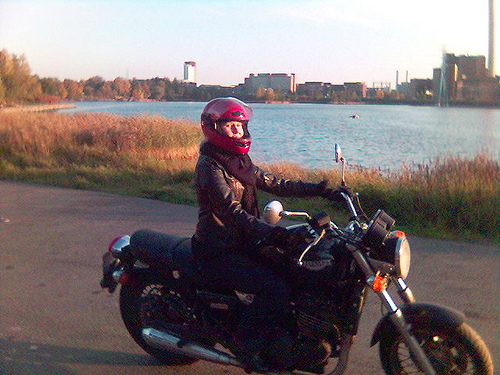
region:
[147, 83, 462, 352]
A person on a motorcycle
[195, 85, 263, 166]
A person wearing a helmet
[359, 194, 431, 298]
The headlight on a motorcycle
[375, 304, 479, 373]
The front tire on a motorcycle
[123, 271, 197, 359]
The rear tire on a motorcycle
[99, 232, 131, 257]
The break light on a motorcycle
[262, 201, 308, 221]
The mirror on a motorcycle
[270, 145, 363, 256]
The handle bars on a motorcycle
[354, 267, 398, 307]
The turn signal on a motorcycle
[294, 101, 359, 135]
Water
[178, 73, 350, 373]
Woman riding a motorcycle.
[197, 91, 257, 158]
Woman wearing red helmet.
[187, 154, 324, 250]
Woman dressed in brown leather jacket.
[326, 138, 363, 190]
Rear view mirror on motorcycle.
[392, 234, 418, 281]
Headlight on front of motorcycle.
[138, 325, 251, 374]
Exhaust pipe on side of motorcycle.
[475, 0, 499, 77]
Manufacturing smoke stack in distance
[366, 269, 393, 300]
Orange signal light in front of motorcycle.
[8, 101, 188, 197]
Grasses growing on side of road next to river.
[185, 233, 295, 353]
Woman dressed in blue jeans.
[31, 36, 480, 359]
person riding motorcycle around lake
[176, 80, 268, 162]
person wearing red helmet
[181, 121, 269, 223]
person wearing scarf around neck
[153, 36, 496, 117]
building beside the lake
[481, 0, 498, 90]
tall chimney on building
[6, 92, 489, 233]
tall brown grass around lake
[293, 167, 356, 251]
person wearing black gloves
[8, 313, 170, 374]
shadow of motorcycle on pavement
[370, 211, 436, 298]
headlight on front of motorcycle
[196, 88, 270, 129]
face shield on helmet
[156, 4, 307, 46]
this is the sky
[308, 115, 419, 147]
this is water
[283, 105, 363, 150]
the water is blue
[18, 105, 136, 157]
these are grasses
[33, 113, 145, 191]
the grasses are green and brown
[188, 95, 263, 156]
this is a helmet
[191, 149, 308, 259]
this is a black jacket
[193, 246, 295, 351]
this is a blue pair of jeans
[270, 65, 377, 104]
these are buildings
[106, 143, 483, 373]
this is a motor bike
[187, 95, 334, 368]
woman in a red helmet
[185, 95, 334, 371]
lady in a red helmet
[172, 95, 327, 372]
woman in a leather jacket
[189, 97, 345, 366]
lady in a leather jacket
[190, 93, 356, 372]
woman on a motorcycle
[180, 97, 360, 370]
lady on a motorcycle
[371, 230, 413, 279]
headlight of a motorcycle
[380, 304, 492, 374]
front tire of a motorcycle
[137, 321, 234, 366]
exhaust pipe of a motorcycle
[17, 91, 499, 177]
a lake beyond the road